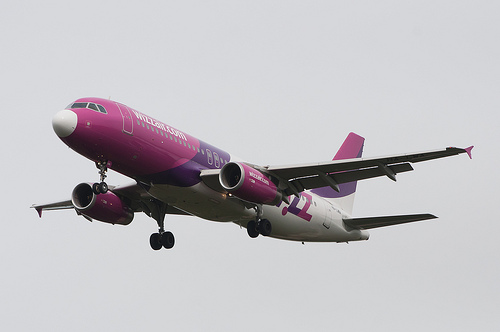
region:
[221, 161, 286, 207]
turbine engine under plane wing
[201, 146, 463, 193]
wing attached to plane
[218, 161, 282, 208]
engine is purple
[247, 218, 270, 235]
black wheels under engine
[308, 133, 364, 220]
tail of plane is purple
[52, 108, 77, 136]
nose of plane is white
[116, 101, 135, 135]
plane door is closed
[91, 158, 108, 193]
landing gear is out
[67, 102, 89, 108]
windshield above nose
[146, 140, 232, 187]
dark purple stripe on plane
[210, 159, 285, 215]
engine of a plane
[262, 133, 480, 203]
wing of a plane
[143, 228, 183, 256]
wheel of the plane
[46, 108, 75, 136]
nose of the plane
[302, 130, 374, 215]
tail of the plane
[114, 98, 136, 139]
door of the plane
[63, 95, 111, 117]
cockpit of the plane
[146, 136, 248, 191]
stripe on the plane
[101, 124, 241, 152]
window on the plane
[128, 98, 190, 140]
letters on the plane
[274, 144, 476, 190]
the wing of a plane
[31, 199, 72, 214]
the wing of a plane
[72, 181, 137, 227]
the engine of a plane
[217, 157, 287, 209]
the engine of a plane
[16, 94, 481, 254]
a plane in the air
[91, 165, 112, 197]
the landing gear of a plane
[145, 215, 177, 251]
the landing gear of a plane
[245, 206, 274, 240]
the landing gear of a plane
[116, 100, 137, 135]
the door of a plane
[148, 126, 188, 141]
the windows on a plane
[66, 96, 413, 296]
the plane is purple and white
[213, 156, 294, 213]
the engine is purple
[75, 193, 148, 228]
the engine is purple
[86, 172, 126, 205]
the whells are two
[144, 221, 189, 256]
the wheels are two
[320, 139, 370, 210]
the tail is purple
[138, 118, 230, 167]
windows are on the side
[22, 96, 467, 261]
engines are two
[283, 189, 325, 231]
letter p is on the tail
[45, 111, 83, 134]
the head is white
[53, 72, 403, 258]
a purple and violet plane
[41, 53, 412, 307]
the plane is flying